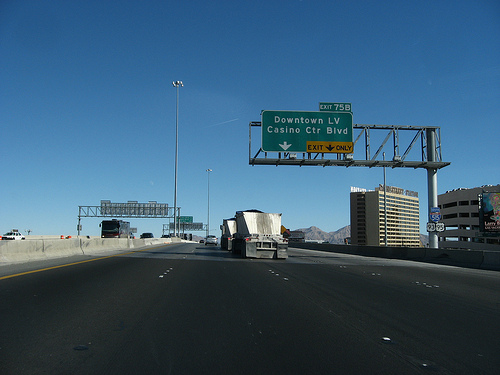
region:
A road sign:
[237, 91, 470, 262]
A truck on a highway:
[223, 202, 300, 265]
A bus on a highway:
[95, 213, 150, 253]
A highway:
[0, 212, 499, 371]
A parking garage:
[425, 174, 498, 262]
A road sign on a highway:
[244, 100, 464, 259]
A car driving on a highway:
[201, 227, 221, 252]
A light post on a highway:
[160, 74, 190, 244]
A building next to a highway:
[344, 180, 424, 252]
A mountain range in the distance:
[158, 222, 452, 252]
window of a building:
[382, 195, 389, 202]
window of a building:
[388, 195, 394, 206]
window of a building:
[402, 202, 409, 212]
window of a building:
[395, 223, 407, 235]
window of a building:
[391, 230, 396, 240]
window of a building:
[407, 238, 413, 248]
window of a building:
[412, 234, 416, 239]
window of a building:
[412, 217, 418, 225]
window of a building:
[406, 227, 412, 234]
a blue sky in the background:
[34, 9, 446, 65]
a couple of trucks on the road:
[219, 210, 287, 258]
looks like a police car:
[4, 230, 24, 241]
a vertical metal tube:
[173, 85, 180, 235]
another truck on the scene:
[100, 220, 137, 239]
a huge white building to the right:
[351, 183, 416, 247]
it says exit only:
[307, 141, 354, 153]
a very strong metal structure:
[247, 123, 444, 253]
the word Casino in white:
[266, 125, 301, 135]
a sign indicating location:
[261, 102, 353, 151]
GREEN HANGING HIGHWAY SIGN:
[257, 106, 359, 156]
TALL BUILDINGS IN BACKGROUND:
[345, 183, 425, 251]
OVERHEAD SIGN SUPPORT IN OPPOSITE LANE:
[73, 201, 185, 219]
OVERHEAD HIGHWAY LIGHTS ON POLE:
[166, 74, 190, 237]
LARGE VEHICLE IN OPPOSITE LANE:
[96, 219, 137, 236]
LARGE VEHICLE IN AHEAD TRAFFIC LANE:
[232, 206, 294, 261]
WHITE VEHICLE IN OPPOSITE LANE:
[0, 229, 31, 241]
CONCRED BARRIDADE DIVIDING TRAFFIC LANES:
[36, 239, 81, 257]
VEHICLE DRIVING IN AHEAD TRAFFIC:
[201, 234, 219, 245]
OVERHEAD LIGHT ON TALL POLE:
[203, 151, 213, 236]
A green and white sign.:
[261, 103, 355, 160]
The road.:
[22, 222, 499, 374]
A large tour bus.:
[95, 218, 138, 242]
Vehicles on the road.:
[8, 209, 380, 291]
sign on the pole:
[254, 109, 352, 154]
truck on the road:
[217, 200, 299, 262]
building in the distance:
[340, 175, 425, 247]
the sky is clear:
[60, 125, 126, 165]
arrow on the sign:
[272, 140, 289, 152]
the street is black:
[205, 299, 255, 322]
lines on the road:
[148, 264, 173, 280]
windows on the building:
[387, 208, 411, 218]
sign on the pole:
[421, 200, 443, 225]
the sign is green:
[314, 137, 331, 139]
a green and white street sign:
[255, 102, 349, 141]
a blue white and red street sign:
[425, 207, 445, 222]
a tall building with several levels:
[342, 182, 421, 256]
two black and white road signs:
[425, 221, 449, 233]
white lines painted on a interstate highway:
[156, 257, 176, 284]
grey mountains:
[302, 213, 347, 248]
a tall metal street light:
[165, 65, 192, 253]